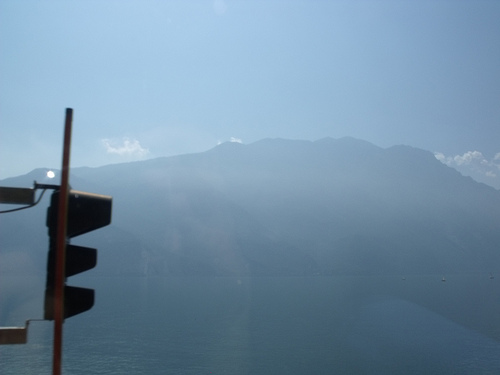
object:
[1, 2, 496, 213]
sky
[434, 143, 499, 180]
cloud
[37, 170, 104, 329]
light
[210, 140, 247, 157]
hill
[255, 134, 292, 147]
hill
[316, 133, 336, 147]
hill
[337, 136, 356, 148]
hill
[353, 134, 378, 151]
hill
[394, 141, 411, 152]
hill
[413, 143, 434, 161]
hill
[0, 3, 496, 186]
sky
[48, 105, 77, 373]
pole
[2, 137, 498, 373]
mountain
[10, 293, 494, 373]
water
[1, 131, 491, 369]
mountani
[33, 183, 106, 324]
street light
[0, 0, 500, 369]
sunlight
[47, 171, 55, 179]
reflection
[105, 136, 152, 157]
cloud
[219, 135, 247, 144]
cloud